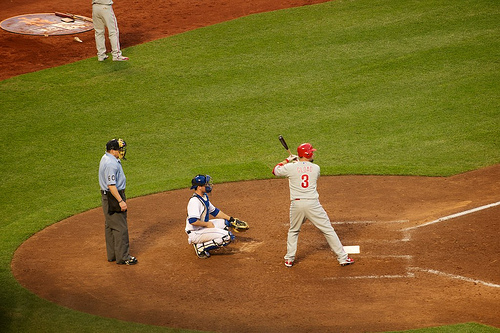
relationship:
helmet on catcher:
[188, 171, 208, 188] [179, 170, 252, 262]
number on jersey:
[296, 172, 312, 191] [278, 157, 326, 198]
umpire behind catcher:
[93, 135, 146, 271] [179, 170, 252, 262]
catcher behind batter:
[179, 170, 252, 262] [272, 130, 361, 271]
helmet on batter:
[296, 141, 319, 157] [272, 130, 361, 271]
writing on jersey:
[291, 163, 315, 174] [278, 157, 326, 198]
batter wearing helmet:
[272, 130, 361, 271] [296, 141, 319, 157]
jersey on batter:
[278, 157, 326, 198] [272, 130, 361, 271]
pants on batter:
[281, 200, 347, 260] [272, 130, 361, 271]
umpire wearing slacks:
[93, 135, 146, 271] [91, 187, 138, 261]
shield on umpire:
[115, 138, 128, 160] [93, 135, 146, 271]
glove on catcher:
[230, 212, 251, 236] [179, 170, 252, 262]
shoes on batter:
[282, 253, 359, 269] [272, 130, 361, 271]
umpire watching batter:
[93, 135, 146, 271] [272, 130, 361, 271]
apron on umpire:
[107, 189, 130, 214] [93, 135, 146, 271]